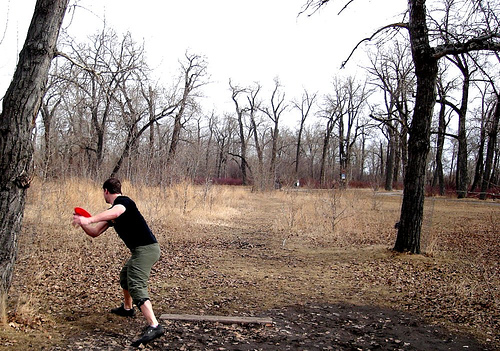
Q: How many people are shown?
A: One.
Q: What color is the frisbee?
A: Red.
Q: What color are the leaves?
A: Brown.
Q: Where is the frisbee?
A: In man's hands.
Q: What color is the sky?
A: Gray.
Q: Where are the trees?
A: In leaves.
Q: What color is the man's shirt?
A: Black.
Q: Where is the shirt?
A: On man.